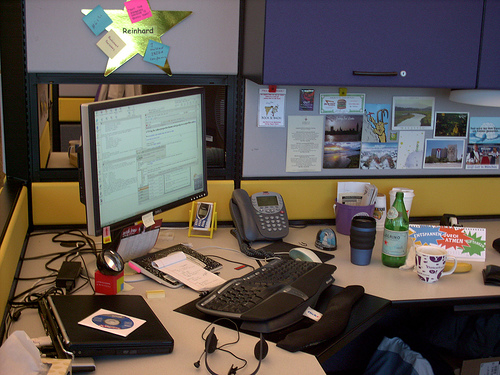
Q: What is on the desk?
A: Computer.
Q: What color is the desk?
A: Brown.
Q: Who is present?
A: Nobody.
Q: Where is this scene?
A: At a messy cubicle in an office.